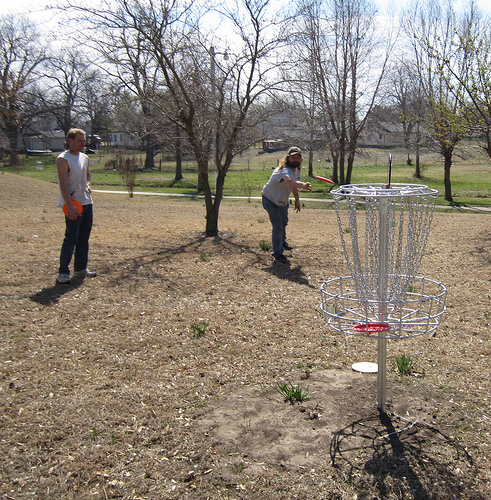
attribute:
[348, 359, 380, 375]
disk — white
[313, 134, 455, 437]
frisbee catcher — metal, large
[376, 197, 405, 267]
chain — silver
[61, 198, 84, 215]
frisbee — orange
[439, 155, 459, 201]
tree trunk — brown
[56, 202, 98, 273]
pants — blue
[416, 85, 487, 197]
tree — dry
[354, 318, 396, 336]
frisbee — white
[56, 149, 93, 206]
shirt — white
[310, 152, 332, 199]
frisbee — metal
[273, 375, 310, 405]
grass — green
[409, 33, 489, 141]
leaves — yellow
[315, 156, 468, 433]
frisbee catcher — large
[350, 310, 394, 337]
frisbee — orange